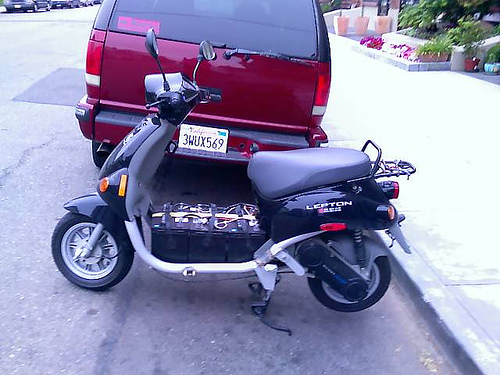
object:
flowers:
[358, 34, 415, 60]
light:
[85, 39, 104, 75]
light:
[85, 72, 102, 88]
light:
[312, 74, 329, 105]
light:
[310, 104, 327, 115]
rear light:
[84, 40, 102, 87]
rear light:
[310, 74, 329, 118]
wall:
[370, 160, 415, 178]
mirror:
[142, 25, 160, 58]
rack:
[371, 158, 416, 177]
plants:
[417, 16, 499, 56]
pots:
[417, 51, 483, 76]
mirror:
[196, 40, 218, 63]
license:
[177, 123, 231, 154]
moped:
[51, 27, 416, 336]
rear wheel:
[306, 235, 392, 313]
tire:
[51, 211, 136, 292]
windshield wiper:
[224, 48, 305, 64]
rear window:
[107, 0, 319, 61]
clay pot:
[333, 15, 351, 36]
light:
[100, 175, 110, 192]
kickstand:
[246, 277, 293, 336]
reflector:
[319, 222, 347, 231]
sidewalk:
[319, 0, 499, 374]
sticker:
[117, 15, 160, 35]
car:
[74, 0, 332, 168]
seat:
[246, 147, 372, 200]